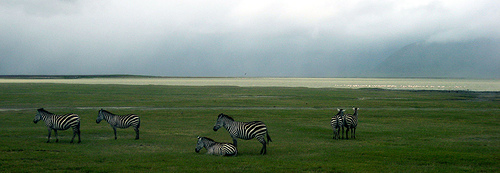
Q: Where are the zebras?
A: In a grassy area.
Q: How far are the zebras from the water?
A: Not very far.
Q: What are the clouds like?
A: Gray skies.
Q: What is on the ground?
A: Zebras.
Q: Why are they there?
A: Grazing.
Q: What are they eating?
A: Grass.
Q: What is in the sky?
A: Clouds.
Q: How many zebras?
A: 6.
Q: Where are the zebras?
A: Ground.